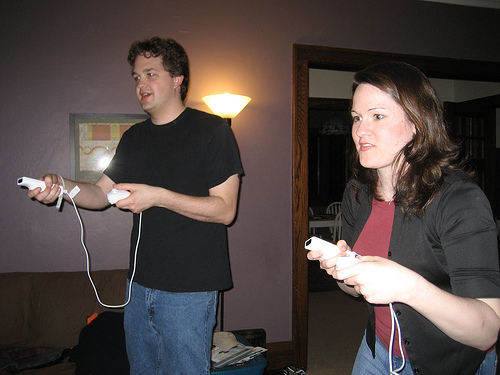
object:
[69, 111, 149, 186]
picture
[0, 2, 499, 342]
wall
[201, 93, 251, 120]
light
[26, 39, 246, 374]
man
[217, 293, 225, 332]
pole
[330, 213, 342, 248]
chair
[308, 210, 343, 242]
table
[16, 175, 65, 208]
wiimote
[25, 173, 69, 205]
man's right hand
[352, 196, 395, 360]
shirt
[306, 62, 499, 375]
woman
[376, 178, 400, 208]
necklace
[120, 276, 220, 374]
jeans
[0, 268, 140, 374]
couch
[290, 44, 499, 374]
door frame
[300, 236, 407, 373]
controller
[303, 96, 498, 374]
other room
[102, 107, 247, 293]
tshirt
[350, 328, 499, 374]
jean pants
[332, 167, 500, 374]
jacket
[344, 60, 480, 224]
hair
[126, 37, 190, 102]
hair